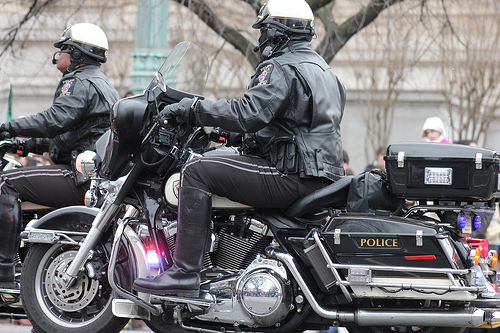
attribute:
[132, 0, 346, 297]
officer — riding, watching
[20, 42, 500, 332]
motorcycle — black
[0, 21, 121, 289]
officer — riding, watching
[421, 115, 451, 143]
person — hooded, watching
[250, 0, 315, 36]
helmet — white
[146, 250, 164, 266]
light — flashing, red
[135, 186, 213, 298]
boot — knee-high, leather, black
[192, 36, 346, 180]
jacket — black, leather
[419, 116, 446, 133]
hood — white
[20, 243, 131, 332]
front-tire — rubber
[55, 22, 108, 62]
helmet — white, black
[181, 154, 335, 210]
pants — black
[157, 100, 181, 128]
glove — leather, black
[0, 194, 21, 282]
boot — tall, black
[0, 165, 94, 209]
pants — black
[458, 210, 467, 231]
light — blue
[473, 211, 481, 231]
light — blue